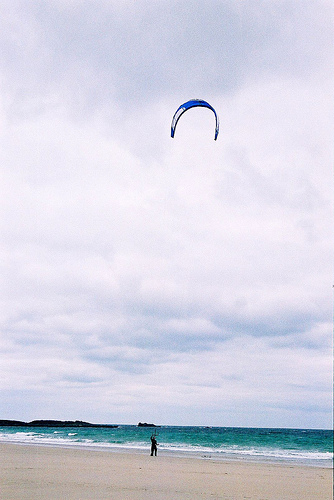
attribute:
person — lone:
[149, 433, 159, 456]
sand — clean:
[0, 440, 334, 498]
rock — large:
[136, 421, 158, 426]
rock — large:
[0, 418, 120, 428]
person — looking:
[149, 434, 160, 455]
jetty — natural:
[0, 418, 162, 428]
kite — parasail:
[162, 93, 226, 141]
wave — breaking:
[1, 430, 332, 460]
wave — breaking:
[52, 428, 64, 434]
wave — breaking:
[66, 430, 80, 436]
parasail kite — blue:
[170, 98, 221, 140]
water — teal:
[2, 423, 333, 459]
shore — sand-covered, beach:
[2, 439, 331, 497]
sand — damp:
[2, 437, 333, 475]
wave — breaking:
[5, 437, 93, 448]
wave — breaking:
[104, 439, 199, 446]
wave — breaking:
[228, 448, 333, 460]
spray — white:
[2, 434, 333, 460]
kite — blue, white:
[166, 95, 226, 143]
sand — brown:
[3, 446, 332, 493]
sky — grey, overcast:
[5, 5, 326, 414]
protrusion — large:
[136, 420, 163, 429]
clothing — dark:
[150, 445, 156, 452]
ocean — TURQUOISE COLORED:
[1, 423, 332, 461]